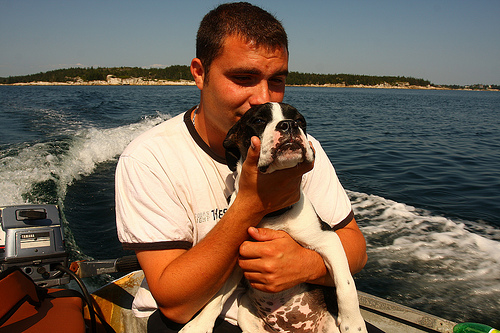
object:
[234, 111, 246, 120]
mouth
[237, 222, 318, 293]
hand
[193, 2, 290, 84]
hair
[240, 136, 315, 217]
hand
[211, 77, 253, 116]
cheek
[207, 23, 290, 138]
face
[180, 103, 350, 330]
dog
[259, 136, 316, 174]
mouth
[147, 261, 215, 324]
elbow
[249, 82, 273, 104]
nose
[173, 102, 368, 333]
puppy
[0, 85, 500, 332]
water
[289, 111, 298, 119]
eye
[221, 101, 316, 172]
face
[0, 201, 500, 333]
boat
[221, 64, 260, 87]
eye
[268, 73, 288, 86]
eye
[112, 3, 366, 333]
man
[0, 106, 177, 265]
wave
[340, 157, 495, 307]
wave